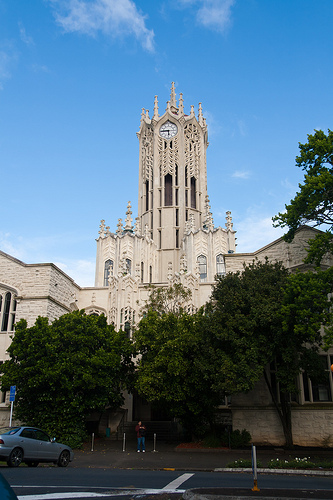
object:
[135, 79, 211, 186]
ornate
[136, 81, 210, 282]
clock tower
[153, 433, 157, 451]
pole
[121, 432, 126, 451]
pole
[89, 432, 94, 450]
pole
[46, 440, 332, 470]
pavement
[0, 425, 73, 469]
car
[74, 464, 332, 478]
curb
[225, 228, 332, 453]
wall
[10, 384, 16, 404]
sign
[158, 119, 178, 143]
clock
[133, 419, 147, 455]
person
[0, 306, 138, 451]
trees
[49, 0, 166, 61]
cloud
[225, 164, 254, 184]
cloud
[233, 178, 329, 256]
cloud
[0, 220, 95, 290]
cloud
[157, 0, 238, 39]
cloud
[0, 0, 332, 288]
sky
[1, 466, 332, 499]
street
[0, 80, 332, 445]
building